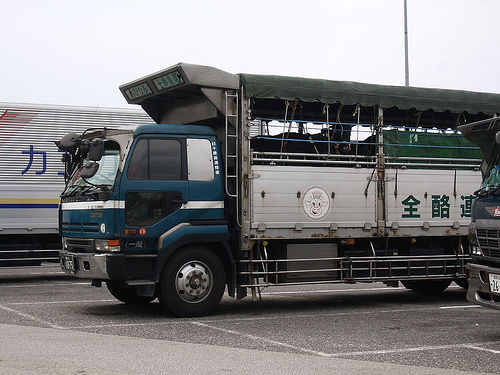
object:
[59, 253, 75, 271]
plate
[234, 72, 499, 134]
tarp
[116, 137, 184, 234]
door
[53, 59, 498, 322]
truck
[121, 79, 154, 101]
signs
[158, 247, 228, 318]
tire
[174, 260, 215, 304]
silver wheel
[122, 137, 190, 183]
window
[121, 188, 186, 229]
window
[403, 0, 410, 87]
pole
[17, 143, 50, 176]
writing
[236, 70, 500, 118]
roof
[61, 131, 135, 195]
windshield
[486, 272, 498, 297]
license plate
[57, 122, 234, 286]
cab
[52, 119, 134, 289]
front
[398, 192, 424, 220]
green writing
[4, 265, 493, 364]
pavement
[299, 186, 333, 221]
logo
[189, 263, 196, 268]
opening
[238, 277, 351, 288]
steps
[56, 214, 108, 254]
grill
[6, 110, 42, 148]
silver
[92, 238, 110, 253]
light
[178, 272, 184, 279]
opening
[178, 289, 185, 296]
opening